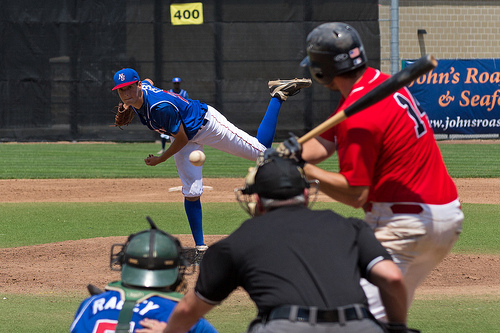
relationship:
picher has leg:
[111, 67, 314, 269] [172, 141, 205, 249]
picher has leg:
[111, 67, 314, 269] [203, 77, 312, 159]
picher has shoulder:
[111, 67, 314, 269] [145, 92, 173, 120]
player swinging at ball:
[299, 20, 464, 316] [188, 150, 206, 167]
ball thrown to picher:
[188, 150, 206, 167] [111, 67, 314, 269]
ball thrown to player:
[188, 150, 206, 167] [299, 20, 464, 316]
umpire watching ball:
[160, 156, 408, 330] [188, 150, 206, 167]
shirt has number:
[322, 67, 458, 202] [391, 85, 431, 142]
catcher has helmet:
[69, 230, 218, 330] [120, 228, 185, 286]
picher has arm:
[111, 67, 314, 269] [144, 108, 189, 167]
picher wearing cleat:
[111, 67, 314, 269] [266, 78, 308, 105]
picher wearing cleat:
[111, 67, 314, 269] [191, 247, 207, 263]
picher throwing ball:
[111, 67, 314, 269] [188, 150, 206, 167]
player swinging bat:
[299, 20, 464, 316] [297, 52, 437, 145]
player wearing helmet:
[299, 20, 464, 316] [308, 23, 368, 80]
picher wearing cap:
[111, 67, 314, 269] [111, 68, 140, 93]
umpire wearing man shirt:
[160, 156, 408, 330] [191, 203, 396, 317]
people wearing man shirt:
[68, 20, 465, 332] [191, 203, 396, 317]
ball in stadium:
[188, 149, 207, 167] [5, 4, 498, 151]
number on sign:
[173, 5, 200, 19] [166, 0, 204, 25]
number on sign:
[391, 86, 431, 137] [166, 0, 204, 25]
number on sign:
[90, 315, 135, 332] [404, 57, 498, 139]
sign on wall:
[166, 0, 204, 25] [378, 4, 498, 134]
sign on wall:
[404, 57, 498, 139] [378, 4, 498, 134]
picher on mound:
[98, 62, 337, 264] [70, 224, 492, 301]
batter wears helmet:
[231, 18, 470, 323] [299, 19, 372, 88]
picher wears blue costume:
[111, 67, 314, 269] [111, 65, 209, 142]